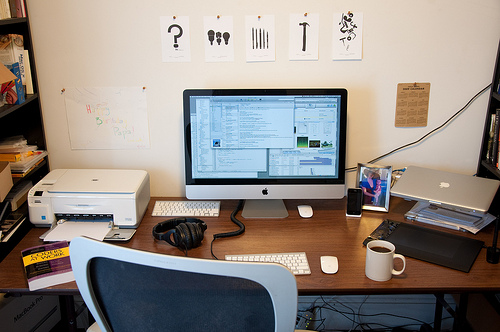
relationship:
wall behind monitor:
[33, 2, 497, 202] [168, 72, 351, 222]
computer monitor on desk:
[176, 83, 356, 220] [1, 195, 498, 330]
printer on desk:
[24, 165, 151, 244] [6, 208, 384, 289]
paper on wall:
[330, 5, 363, 63] [30, 1, 480, 182]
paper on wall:
[391, 80, 431, 128] [30, 1, 480, 182]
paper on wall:
[288, 10, 317, 60] [30, 1, 480, 182]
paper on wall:
[241, 10, 275, 62] [30, 1, 480, 182]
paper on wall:
[196, 6, 231, 62] [30, 1, 480, 182]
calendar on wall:
[376, 77, 441, 141] [368, 28, 471, 173]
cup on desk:
[362, 239, 406, 282] [1, 195, 498, 330]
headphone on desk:
[152, 217, 208, 250] [16, 181, 486, 296]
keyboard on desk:
[152, 196, 219, 217] [1, 186, 498, 292]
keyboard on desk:
[224, 250, 309, 276] [1, 186, 498, 292]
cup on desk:
[362, 236, 407, 282] [80, 212, 380, 277]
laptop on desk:
[391, 163, 498, 213] [1, 186, 498, 292]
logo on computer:
[256, 186, 281, 197] [185, 82, 346, 203]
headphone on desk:
[146, 215, 211, 250] [1, 186, 498, 292]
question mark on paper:
[170, 27, 180, 44] [154, 10, 199, 63]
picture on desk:
[354, 162, 391, 214] [1, 186, 498, 292]